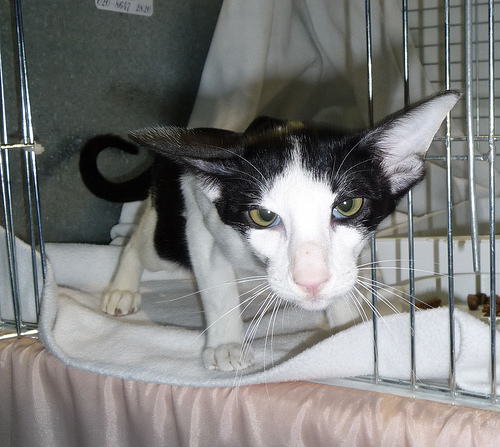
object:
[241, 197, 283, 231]
eye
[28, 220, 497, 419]
blanket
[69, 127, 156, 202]
tail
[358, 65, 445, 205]
ear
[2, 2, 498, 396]
cage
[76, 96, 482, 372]
cat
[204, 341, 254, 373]
right paw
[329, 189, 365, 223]
eye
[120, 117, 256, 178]
ear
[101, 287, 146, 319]
foot